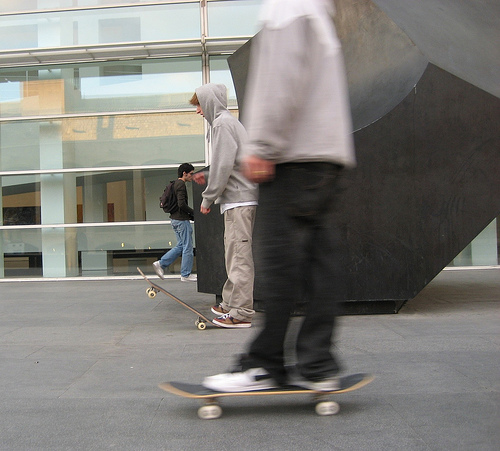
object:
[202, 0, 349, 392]
person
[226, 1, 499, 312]
sculpture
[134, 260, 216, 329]
skateboard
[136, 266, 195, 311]
up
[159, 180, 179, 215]
backpack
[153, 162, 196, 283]
man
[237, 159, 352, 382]
pants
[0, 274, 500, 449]
sidewalk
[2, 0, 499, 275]
building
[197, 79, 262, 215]
sweatshirt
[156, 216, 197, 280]
pants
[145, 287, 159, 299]
wheels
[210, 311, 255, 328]
foot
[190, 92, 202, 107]
hair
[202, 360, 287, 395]
sneaker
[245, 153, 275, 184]
hand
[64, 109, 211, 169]
window